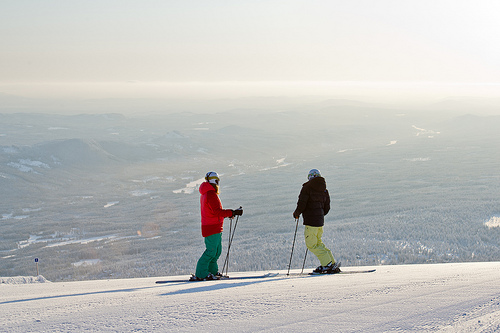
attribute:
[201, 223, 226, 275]
pants — green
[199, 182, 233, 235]
jacket — red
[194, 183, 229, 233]
jacket — red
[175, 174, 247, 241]
coat — red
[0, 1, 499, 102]
sky — distant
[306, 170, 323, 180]
hat — wool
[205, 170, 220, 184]
hat — wool